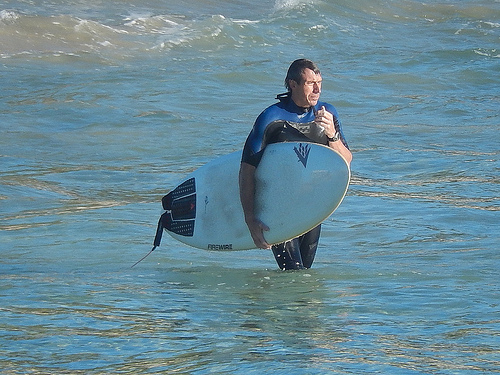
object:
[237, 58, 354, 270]
man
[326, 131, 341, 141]
watch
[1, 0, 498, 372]
waters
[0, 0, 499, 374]
sea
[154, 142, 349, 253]
white board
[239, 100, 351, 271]
wetsuit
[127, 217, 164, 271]
cord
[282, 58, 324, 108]
man looking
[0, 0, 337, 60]
white gray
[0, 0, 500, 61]
wave